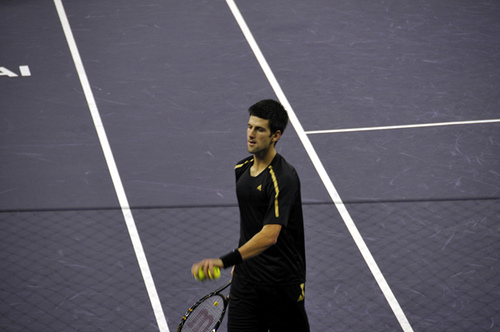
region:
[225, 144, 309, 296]
a black shirt with a yellow stripe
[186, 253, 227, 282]
two yellow balls in a hand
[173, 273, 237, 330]
a yellow and black racket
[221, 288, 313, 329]
black shorts on a man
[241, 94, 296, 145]
black hair on a man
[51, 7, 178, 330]
a white stripe on a tennis court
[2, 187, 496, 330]
the shadow of a chain link fence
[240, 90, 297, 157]
the head of a man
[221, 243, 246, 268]
a black wristband on a wrist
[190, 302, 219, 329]
a "W" on a tennis racket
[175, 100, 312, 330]
man is playing tennis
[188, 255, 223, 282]
man is holding balls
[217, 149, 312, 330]
players uniform is black and gold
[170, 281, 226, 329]
racket is black, gold, and white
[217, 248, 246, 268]
Wristband is black cloth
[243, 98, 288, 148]
man has short black hair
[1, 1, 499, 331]
tennis courts are blue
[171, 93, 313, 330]
player is walking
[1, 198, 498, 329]
chain link fence shadow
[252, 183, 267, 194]
gold logo on shirt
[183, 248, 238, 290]
the man is holding two tennis balls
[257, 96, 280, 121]
the man has hair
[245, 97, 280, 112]
his hair is dark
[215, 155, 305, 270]
the shirt is black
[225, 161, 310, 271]
the man wears a shirt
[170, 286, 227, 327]
the racket is black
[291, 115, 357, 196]
the lines are white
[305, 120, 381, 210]
the lines are on the court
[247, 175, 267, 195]
the shirt has a logo on it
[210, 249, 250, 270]
the wrist band is black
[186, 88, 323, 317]
tennis player on court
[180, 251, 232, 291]
two balls in hand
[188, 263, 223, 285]
yellow balls under fingers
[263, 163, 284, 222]
yellow stripe on shirt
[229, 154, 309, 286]
short sleeved black tee shirt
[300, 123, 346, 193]
white line on court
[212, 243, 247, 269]
black band on wrist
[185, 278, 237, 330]
tennis racket with white string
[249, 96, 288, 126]
black hair on player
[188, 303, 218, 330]
letter on racket strings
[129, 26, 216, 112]
The ground is black.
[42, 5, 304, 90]
Lines are on the ground.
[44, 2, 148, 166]
The lines are white.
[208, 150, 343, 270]
The person is wearing a black top.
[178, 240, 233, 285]
The person is holding tennis balls.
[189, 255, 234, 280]
The balls are chartreuse.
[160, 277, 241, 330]
The person is carrying a tennis racket.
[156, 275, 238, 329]
The racket is black.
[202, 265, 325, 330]
The person is wear shorts.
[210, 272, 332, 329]
The person is wearing black shorts.